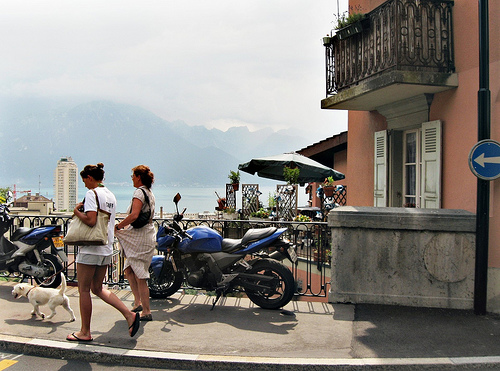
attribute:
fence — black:
[154, 220, 334, 297]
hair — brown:
[132, 163, 154, 187]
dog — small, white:
[8, 272, 76, 324]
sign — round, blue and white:
[465, 138, 499, 181]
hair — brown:
[80, 163, 104, 183]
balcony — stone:
[317, 1, 459, 133]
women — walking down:
[49, 148, 211, 368]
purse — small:
[108, 180, 163, 229]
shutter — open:
[419, 117, 441, 208]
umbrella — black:
[231, 150, 346, 192]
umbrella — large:
[237, 143, 343, 200]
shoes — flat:
[130, 301, 156, 324]